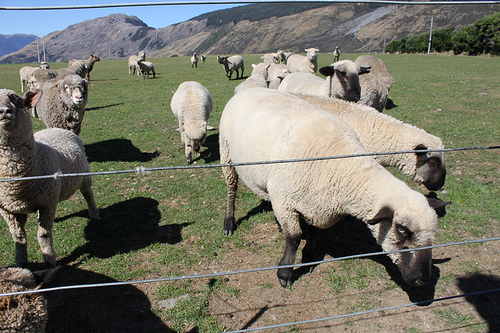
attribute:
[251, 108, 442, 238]
sheep — bright, fluffy, herd, grey, group, overgrown, eating, flock, woolly, gray, small, looking, many, white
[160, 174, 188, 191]
grass — worn, short, clear, green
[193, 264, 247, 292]
patch — dirt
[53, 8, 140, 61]
mountain — dark, background, without trees, rising, big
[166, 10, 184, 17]
sky — bright, cloudless, clear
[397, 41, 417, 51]
shrubbery — green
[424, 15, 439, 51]
pole — wooden, power, tall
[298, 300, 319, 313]
soil — brown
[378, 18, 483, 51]
trees — line, leafy, green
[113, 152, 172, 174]
fence — electric, grey